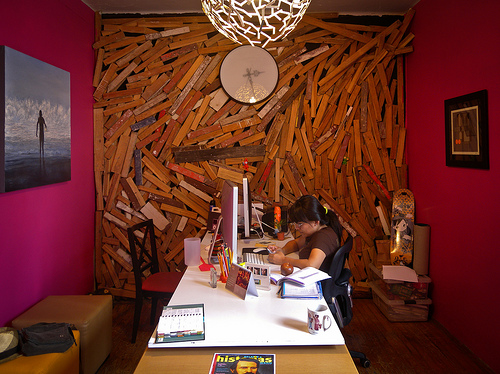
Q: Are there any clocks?
A: Yes, there is a clock.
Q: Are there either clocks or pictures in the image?
A: Yes, there is a clock.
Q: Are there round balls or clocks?
A: Yes, there is a round clock.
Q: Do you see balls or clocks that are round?
A: Yes, the clock is round.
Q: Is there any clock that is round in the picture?
A: Yes, there is a round clock.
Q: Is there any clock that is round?
A: Yes, there is a clock that is round.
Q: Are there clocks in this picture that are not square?
A: Yes, there is a round clock.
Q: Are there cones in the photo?
A: No, there are no cones.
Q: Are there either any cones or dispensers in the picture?
A: No, there are no cones or dispensers.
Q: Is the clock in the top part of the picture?
A: Yes, the clock is in the top of the image.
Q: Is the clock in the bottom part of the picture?
A: No, the clock is in the top of the image.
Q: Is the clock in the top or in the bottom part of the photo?
A: The clock is in the top of the image.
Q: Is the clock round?
A: Yes, the clock is round.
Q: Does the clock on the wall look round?
A: Yes, the clock is round.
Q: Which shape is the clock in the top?
A: The clock is round.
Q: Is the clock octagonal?
A: No, the clock is round.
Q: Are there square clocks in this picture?
A: No, there is a clock but it is round.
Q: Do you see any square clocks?
A: No, there is a clock but it is round.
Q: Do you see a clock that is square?
A: No, there is a clock but it is round.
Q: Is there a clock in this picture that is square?
A: No, there is a clock but it is round.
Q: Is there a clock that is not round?
A: No, there is a clock but it is round.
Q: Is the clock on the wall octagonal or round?
A: The clock is round.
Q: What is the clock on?
A: The clock is on the wall.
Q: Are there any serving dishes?
A: No, there are no serving dishes.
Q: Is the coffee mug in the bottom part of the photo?
A: Yes, the coffee mug is in the bottom of the image.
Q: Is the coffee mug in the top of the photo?
A: No, the coffee mug is in the bottom of the image.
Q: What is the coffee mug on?
A: The coffee mug is on the desk.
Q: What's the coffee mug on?
A: The coffee mug is on the desk.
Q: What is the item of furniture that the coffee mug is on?
A: The piece of furniture is a desk.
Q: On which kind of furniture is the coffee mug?
A: The coffee mug is on the desk.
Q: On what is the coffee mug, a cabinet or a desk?
A: The coffee mug is on a desk.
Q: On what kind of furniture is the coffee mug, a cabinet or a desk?
A: The coffee mug is on a desk.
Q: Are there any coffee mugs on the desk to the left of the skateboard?
A: Yes, there is a coffee mug on the desk.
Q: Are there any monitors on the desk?
A: No, there is a coffee mug on the desk.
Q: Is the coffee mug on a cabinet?
A: No, the coffee mug is on the desk.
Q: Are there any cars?
A: No, there are no cars.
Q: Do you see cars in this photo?
A: No, there are no cars.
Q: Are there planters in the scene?
A: No, there are no planters.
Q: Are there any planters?
A: No, there are no planters.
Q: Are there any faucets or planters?
A: No, there are no planters or faucets.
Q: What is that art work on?
A: The art work is on the wall.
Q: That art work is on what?
A: The art work is on the wall.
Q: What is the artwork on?
A: The art work is on the wall.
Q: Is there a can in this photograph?
A: No, there are no cans.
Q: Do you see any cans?
A: No, there are no cans.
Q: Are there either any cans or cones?
A: No, there are no cans or cones.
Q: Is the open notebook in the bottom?
A: Yes, the notebook is in the bottom of the image.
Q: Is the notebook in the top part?
A: No, the notebook is in the bottom of the image.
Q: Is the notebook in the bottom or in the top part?
A: The notebook is in the bottom of the image.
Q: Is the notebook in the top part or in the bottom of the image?
A: The notebook is in the bottom of the image.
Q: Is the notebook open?
A: Yes, the notebook is open.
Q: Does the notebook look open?
A: Yes, the notebook is open.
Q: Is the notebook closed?
A: No, the notebook is open.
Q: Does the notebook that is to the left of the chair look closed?
A: No, the notebook is open.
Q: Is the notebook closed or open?
A: The notebook is open.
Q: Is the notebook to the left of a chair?
A: Yes, the notebook is to the left of a chair.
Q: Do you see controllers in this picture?
A: No, there are no controllers.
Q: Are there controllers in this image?
A: No, there are no controllers.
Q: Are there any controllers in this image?
A: No, there are no controllers.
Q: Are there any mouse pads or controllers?
A: No, there are no controllers or mouse pads.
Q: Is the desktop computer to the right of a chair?
A: Yes, the desktop computer is to the right of a chair.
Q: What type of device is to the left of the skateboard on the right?
A: The device is a desktop computer.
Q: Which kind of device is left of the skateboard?
A: The device is a desktop computer.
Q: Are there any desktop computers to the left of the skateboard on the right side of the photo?
A: Yes, there is a desktop computer to the left of the skateboard.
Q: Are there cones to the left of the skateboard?
A: No, there is a desktop computer to the left of the skateboard.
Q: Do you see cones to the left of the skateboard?
A: No, there is a desktop computer to the left of the skateboard.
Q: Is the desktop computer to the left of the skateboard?
A: Yes, the desktop computer is to the left of the skateboard.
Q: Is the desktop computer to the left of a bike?
A: No, the desktop computer is to the left of the skateboard.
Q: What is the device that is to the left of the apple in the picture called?
A: The device is a desktop computer.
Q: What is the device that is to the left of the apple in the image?
A: The device is a desktop computer.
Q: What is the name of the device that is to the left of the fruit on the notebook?
A: The device is a desktop computer.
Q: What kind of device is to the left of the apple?
A: The device is a desktop computer.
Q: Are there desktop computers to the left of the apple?
A: Yes, there is a desktop computer to the left of the apple.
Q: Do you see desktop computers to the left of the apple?
A: Yes, there is a desktop computer to the left of the apple.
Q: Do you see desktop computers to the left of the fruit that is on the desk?
A: Yes, there is a desktop computer to the left of the apple.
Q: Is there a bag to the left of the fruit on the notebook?
A: No, there is a desktop computer to the left of the apple.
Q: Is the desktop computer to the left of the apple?
A: Yes, the desktop computer is to the left of the apple.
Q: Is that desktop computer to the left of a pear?
A: No, the desktop computer is to the left of the apple.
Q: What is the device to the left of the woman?
A: The device is a desktop computer.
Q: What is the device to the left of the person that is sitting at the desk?
A: The device is a desktop computer.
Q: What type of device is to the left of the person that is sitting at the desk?
A: The device is a desktop computer.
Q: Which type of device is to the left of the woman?
A: The device is a desktop computer.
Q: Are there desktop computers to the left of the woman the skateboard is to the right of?
A: Yes, there is a desktop computer to the left of the woman.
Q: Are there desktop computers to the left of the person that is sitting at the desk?
A: Yes, there is a desktop computer to the left of the woman.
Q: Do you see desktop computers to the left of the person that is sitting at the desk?
A: Yes, there is a desktop computer to the left of the woman.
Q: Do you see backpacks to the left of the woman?
A: No, there is a desktop computer to the left of the woman.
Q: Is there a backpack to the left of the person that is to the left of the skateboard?
A: No, there is a desktop computer to the left of the woman.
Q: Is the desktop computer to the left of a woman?
A: Yes, the desktop computer is to the left of a woman.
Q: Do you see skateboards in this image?
A: Yes, there is a skateboard.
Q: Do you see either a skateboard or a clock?
A: Yes, there is a skateboard.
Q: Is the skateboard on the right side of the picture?
A: Yes, the skateboard is on the right of the image.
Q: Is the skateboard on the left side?
A: No, the skateboard is on the right of the image.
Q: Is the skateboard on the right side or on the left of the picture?
A: The skateboard is on the right of the image.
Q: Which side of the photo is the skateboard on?
A: The skateboard is on the right of the image.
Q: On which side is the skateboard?
A: The skateboard is on the right of the image.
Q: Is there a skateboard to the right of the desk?
A: Yes, there is a skateboard to the right of the desk.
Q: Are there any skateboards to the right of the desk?
A: Yes, there is a skateboard to the right of the desk.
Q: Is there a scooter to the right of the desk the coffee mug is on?
A: No, there is a skateboard to the right of the desk.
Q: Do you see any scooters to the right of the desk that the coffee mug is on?
A: No, there is a skateboard to the right of the desk.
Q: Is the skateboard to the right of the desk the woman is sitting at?
A: Yes, the skateboard is to the right of the desk.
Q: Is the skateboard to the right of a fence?
A: No, the skateboard is to the right of the desk.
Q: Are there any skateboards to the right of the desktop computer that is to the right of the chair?
A: Yes, there is a skateboard to the right of the desktop computer.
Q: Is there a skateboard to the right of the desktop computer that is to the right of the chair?
A: Yes, there is a skateboard to the right of the desktop computer.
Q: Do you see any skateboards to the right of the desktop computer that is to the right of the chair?
A: Yes, there is a skateboard to the right of the desktop computer.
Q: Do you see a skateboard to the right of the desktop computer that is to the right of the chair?
A: Yes, there is a skateboard to the right of the desktop computer.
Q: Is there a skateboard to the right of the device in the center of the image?
A: Yes, there is a skateboard to the right of the desktop computer.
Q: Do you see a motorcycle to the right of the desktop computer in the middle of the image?
A: No, there is a skateboard to the right of the desktop computer.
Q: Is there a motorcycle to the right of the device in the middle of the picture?
A: No, there is a skateboard to the right of the desktop computer.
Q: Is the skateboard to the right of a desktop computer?
A: Yes, the skateboard is to the right of a desktop computer.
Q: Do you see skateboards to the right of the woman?
A: Yes, there is a skateboard to the right of the woman.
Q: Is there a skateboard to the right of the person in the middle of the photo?
A: Yes, there is a skateboard to the right of the woman.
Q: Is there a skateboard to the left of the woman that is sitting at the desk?
A: No, the skateboard is to the right of the woman.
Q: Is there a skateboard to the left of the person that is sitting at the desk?
A: No, the skateboard is to the right of the woman.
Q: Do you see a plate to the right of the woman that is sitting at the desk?
A: No, there is a skateboard to the right of the woman.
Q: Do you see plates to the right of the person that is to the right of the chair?
A: No, there is a skateboard to the right of the woman.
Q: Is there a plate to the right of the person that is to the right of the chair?
A: No, there is a skateboard to the right of the woman.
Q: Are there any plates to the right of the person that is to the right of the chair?
A: No, there is a skateboard to the right of the woman.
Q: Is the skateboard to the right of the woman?
A: Yes, the skateboard is to the right of the woman.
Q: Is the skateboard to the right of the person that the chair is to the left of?
A: Yes, the skateboard is to the right of the woman.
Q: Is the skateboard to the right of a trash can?
A: No, the skateboard is to the right of the woman.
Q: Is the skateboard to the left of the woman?
A: No, the skateboard is to the right of the woman.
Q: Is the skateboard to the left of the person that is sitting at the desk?
A: No, the skateboard is to the right of the woman.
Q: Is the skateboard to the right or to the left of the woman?
A: The skateboard is to the right of the woman.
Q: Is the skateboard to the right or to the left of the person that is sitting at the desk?
A: The skateboard is to the right of the woman.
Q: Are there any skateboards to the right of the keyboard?
A: Yes, there is a skateboard to the right of the keyboard.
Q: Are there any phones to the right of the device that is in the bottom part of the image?
A: No, there is a skateboard to the right of the keyboard.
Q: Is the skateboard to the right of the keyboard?
A: Yes, the skateboard is to the right of the keyboard.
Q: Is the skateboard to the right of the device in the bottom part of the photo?
A: Yes, the skateboard is to the right of the keyboard.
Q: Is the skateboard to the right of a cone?
A: No, the skateboard is to the right of the keyboard.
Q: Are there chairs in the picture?
A: Yes, there is a chair.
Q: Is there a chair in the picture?
A: Yes, there is a chair.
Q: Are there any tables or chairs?
A: Yes, there is a chair.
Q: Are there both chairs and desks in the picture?
A: Yes, there are both a chair and a desk.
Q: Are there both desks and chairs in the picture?
A: Yes, there are both a chair and a desk.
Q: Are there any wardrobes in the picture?
A: No, there are no wardrobes.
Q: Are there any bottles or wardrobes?
A: No, there are no wardrobes or bottles.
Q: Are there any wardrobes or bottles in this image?
A: No, there are no wardrobes or bottles.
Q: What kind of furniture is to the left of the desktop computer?
A: The piece of furniture is a chair.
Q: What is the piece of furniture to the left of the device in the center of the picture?
A: The piece of furniture is a chair.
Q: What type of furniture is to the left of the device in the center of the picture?
A: The piece of furniture is a chair.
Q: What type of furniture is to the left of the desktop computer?
A: The piece of furniture is a chair.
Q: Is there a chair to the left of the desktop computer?
A: Yes, there is a chair to the left of the desktop computer.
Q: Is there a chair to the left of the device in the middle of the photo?
A: Yes, there is a chair to the left of the desktop computer.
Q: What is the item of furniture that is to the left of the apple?
A: The piece of furniture is a chair.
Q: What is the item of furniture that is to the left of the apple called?
A: The piece of furniture is a chair.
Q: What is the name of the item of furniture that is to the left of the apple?
A: The piece of furniture is a chair.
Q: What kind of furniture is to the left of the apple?
A: The piece of furniture is a chair.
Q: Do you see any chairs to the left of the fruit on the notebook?
A: Yes, there is a chair to the left of the apple.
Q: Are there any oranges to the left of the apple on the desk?
A: No, there is a chair to the left of the apple.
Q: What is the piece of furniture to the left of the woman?
A: The piece of furniture is a chair.